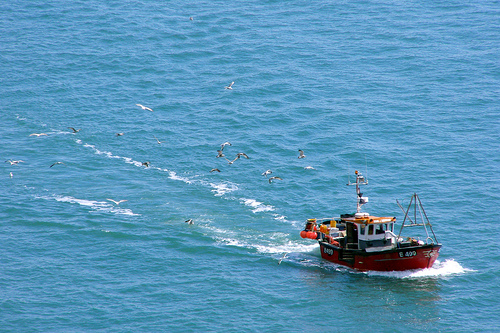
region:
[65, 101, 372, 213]
seagulls follow a fishing boat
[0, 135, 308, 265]
the wake of the boat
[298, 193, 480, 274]
red and white fishing boat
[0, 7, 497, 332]
water is a clear blue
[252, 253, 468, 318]
boat reflected in the water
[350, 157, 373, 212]
A lookout area mounted on a pole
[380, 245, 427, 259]
The identification of the boat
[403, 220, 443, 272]
the bow of the fishing boat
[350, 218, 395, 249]
where the captain steers the boat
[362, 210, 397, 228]
orange mount for lights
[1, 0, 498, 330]
beautiful blue water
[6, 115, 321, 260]
wake behind a boat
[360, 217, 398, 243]
the white cabin of a boat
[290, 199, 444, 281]
a red and white boat on the water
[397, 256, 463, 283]
white water hitting the front of a boat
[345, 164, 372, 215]
a pole on the top of a boat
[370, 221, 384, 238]
a window in the abin of a boat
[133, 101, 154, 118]
a white bird in the air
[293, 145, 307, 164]
a grey and white bird following a boat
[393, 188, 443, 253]
a tripod on the front end of a boat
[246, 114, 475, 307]
a fishing boat out on the water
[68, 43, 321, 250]
some birds fly near the boat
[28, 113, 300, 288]
a trail of where the boat has traveled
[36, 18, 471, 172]
the water is blue in color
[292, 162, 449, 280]
the fishing boat is red and white in color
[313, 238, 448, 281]
the bottom of the fishing boat is red in color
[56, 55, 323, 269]
a flock of birds fly near the boat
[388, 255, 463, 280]
the water splashing appears white in color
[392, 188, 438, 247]
a tri-pod sits on the boat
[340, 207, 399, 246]
the boats cabin is white in color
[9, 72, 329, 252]
flock of seagulls following fishing boat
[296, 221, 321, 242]
red buoys on fishing boat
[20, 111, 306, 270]
wave ripples created by fishing boat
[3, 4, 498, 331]
ocean is blue and calm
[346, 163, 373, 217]
antenna on top of fishing boat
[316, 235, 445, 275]
body of fishing boat is red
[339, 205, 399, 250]
captain's quarter of boat are white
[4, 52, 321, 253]
flock of seagulls are flying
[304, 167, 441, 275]
fishing boat is moving through the ocean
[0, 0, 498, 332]
A large body of water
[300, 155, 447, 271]
A red and white boat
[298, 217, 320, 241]
some orange buoys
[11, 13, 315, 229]
A flock of seagulls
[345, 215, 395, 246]
the bridge of the boat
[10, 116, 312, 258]
some ripples in the water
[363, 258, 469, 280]
A splash of water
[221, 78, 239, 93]
A seagull in the sky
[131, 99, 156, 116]
A seagull in the sky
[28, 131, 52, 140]
A seagull in the sky